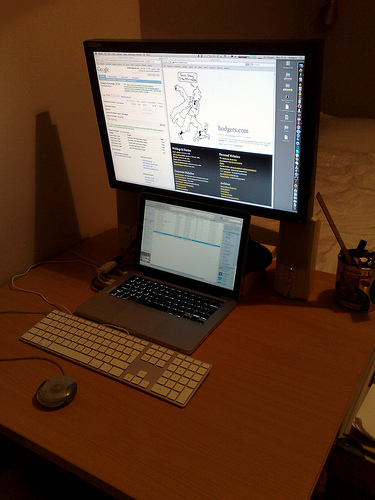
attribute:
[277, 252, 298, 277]
light — on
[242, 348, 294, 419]
desk — brown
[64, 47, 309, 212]
screen — black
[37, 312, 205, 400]
keyboard — gray, white, silver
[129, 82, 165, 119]
paper — white